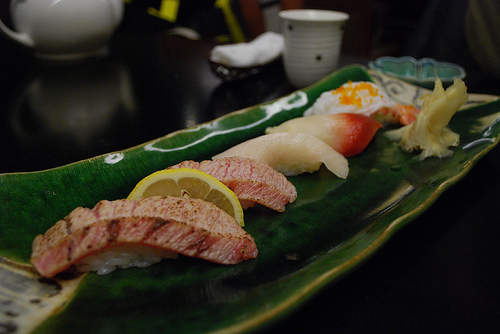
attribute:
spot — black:
[313, 52, 326, 65]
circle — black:
[313, 52, 328, 64]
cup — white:
[278, 5, 357, 92]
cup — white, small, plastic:
[278, 5, 351, 87]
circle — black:
[315, 49, 325, 68]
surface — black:
[21, 70, 131, 136]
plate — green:
[11, 55, 498, 307]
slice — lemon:
[124, 163, 257, 233]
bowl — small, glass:
[370, 51, 473, 101]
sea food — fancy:
[28, 77, 387, 275]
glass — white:
[277, 6, 356, 95]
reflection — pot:
[5, 55, 135, 165]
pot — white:
[0, 0, 134, 66]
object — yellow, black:
[146, 0, 257, 40]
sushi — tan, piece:
[208, 124, 355, 190]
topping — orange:
[329, 74, 390, 120]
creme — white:
[297, 78, 395, 122]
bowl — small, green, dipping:
[365, 50, 466, 93]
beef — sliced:
[27, 189, 261, 279]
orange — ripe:
[121, 168, 246, 231]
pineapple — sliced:
[230, 114, 379, 184]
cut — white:
[276, 6, 350, 93]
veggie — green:
[304, 180, 377, 243]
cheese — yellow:
[335, 78, 386, 113]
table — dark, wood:
[7, 64, 192, 130]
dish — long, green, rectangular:
[3, 63, 499, 328]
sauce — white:
[312, 75, 388, 117]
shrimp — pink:
[315, 110, 382, 160]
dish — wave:
[308, 186, 404, 235]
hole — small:
[309, 50, 325, 65]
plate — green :
[8, 73, 488, 332]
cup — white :
[282, 12, 346, 84]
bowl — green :
[371, 56, 468, 96]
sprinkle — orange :
[309, 76, 402, 116]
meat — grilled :
[39, 199, 255, 271]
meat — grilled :
[178, 159, 299, 212]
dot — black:
[310, 48, 324, 64]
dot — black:
[282, 19, 296, 31]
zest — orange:
[330, 75, 380, 107]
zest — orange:
[333, 77, 380, 111]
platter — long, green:
[6, 52, 498, 328]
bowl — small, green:
[362, 44, 472, 98]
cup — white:
[272, 3, 361, 88]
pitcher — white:
[13, 1, 125, 44]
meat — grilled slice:
[36, 201, 251, 283]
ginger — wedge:
[384, 100, 468, 164]